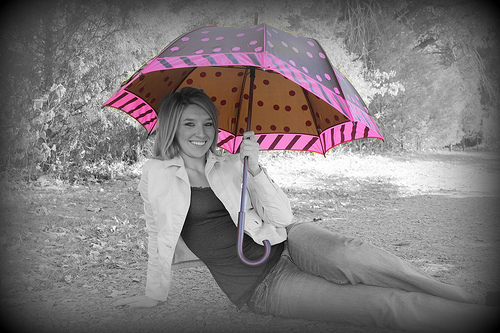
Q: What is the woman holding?
A: An umbrella.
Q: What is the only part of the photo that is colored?
A: The umbrella.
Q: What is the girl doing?
A: Posing.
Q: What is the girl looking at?
A: Camera.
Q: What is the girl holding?
A: Umbrella.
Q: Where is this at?
A: Woods.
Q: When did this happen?
A: During the day time.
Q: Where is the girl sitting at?
A: Ground.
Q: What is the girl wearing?
A: Coat.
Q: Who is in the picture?
A: A lady.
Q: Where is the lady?
A: Under the umbrella?.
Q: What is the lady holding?
A: An umbrella.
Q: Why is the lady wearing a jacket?
A: It's cold.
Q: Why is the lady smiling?
A: She is happy.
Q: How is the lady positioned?
A: She is laying on the ground.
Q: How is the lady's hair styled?
A: The lady is wearing it down.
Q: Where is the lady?
A: The lady is on the ground.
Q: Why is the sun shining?
A: It's a nice day.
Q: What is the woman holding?
A: An umbrella.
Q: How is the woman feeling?
A: Happy.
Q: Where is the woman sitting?
A: On the ground.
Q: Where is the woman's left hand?
A: On the umbrella.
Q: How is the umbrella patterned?
A: With polka dots and stripes.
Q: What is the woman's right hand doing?
A: Supporting her.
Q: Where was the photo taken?
A: In a park.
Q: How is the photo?
A: Clear.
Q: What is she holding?
A: Umbrella.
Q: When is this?
A: Daytime.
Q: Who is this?
A: Lady.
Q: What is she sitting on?
A: The ground.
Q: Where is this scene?
A: In a park.